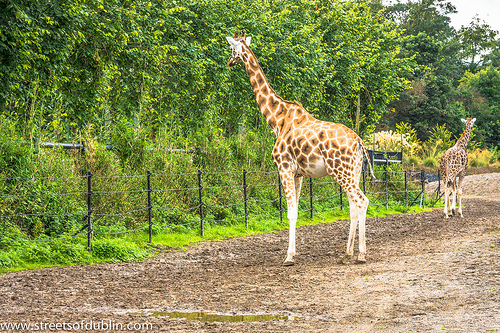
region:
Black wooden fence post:
[56, 154, 116, 286]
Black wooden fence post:
[129, 160, 171, 258]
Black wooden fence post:
[170, 168, 220, 240]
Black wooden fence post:
[225, 160, 262, 239]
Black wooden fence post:
[264, 165, 299, 251]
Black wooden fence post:
[301, 174, 331, 229]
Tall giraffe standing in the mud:
[211, 29, 395, 293]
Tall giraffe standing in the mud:
[419, 99, 492, 248]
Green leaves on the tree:
[26, 23, 101, 141]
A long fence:
[62, 158, 246, 250]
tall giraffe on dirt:
[213, 44, 376, 251]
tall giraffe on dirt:
[431, 99, 475, 212]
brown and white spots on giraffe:
[294, 115, 348, 162]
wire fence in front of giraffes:
[4, 162, 459, 268]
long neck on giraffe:
[230, 27, 292, 131]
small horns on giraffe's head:
[219, 15, 256, 33]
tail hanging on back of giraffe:
[355, 155, 397, 181]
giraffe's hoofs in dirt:
[273, 247, 398, 268]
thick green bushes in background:
[356, 110, 419, 166]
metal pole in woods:
[49, 131, 178, 161]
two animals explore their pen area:
[35, 15, 483, 285]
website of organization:
[0, 311, 161, 326]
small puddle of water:
[170, 301, 280, 321]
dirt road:
[325, 271, 486, 321]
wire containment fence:
[2, 165, 262, 241]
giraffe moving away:
[430, 110, 480, 225]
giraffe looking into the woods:
[216, 21, 387, 271]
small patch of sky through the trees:
[441, 0, 496, 35]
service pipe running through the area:
[37, 130, 207, 157]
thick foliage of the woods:
[23, 2, 213, 137]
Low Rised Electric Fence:
[3, 165, 443, 254]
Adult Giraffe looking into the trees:
[218, 31, 378, 272]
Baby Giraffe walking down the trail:
[435, 115, 479, 217]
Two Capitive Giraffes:
[222, 30, 478, 267]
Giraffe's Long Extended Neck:
[235, 38, 290, 135]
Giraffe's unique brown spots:
[284, 127, 350, 171]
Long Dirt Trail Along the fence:
[12, 169, 497, 331]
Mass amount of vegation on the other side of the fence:
[1, 0, 436, 211]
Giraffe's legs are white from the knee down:
[275, 212, 378, 262]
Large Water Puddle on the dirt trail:
[96, 297, 300, 329]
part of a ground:
[382, 258, 420, 308]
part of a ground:
[412, 253, 433, 285]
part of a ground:
[388, 256, 409, 293]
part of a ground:
[390, 275, 417, 310]